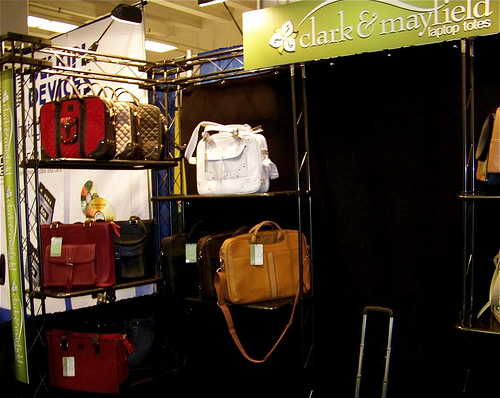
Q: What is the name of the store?
A: Clark & Mayfield.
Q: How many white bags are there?
A: One.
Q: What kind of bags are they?
A: Laptop totes.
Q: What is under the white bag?
A: Tan bag.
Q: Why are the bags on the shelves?
A: To show customers.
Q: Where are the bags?
A: On shelves.